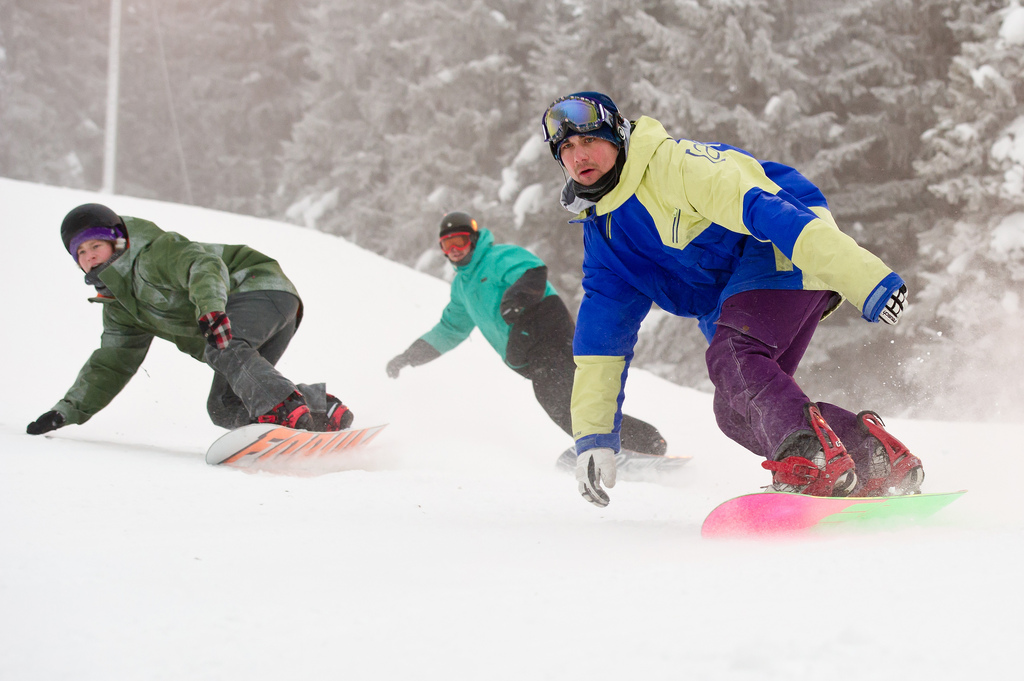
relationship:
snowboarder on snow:
[24, 204, 355, 434] [7, 169, 1021, 671]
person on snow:
[386, 214, 666, 458] [7, 169, 1021, 671]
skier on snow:
[539, 92, 964, 539] [7, 169, 1021, 671]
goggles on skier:
[540, 95, 615, 144] [517, 78, 969, 539]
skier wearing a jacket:
[539, 92, 964, 539] [564, 150, 889, 326]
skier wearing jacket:
[539, 92, 964, 539] [564, 122, 900, 444]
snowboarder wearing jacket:
[24, 204, 355, 434] [45, 242, 294, 402]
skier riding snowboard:
[539, 92, 964, 539] [697, 491, 968, 539]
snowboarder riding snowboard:
[24, 204, 355, 434] [209, 418, 393, 471]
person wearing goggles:
[376, 214, 670, 487] [423, 227, 484, 251]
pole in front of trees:
[99, 0, 123, 198] [17, 9, 964, 398]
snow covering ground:
[0, 188, 1021, 671] [30, 180, 955, 675]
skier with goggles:
[539, 92, 964, 539] [529, 93, 620, 146]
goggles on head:
[529, 93, 620, 146] [546, 85, 627, 178]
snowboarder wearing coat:
[24, 204, 355, 434] [47, 212, 305, 424]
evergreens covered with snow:
[0, 0, 1024, 424] [2, 0, 1011, 418]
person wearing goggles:
[386, 214, 666, 458] [428, 229, 485, 256]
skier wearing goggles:
[539, 92, 964, 539] [533, 89, 633, 139]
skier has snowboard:
[539, 92, 964, 539] [687, 471, 977, 538]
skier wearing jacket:
[539, 92, 964, 539] [538, 83, 910, 457]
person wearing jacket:
[386, 214, 666, 458] [406, 229, 575, 364]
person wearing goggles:
[386, 214, 666, 458] [438, 214, 482, 256]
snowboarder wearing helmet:
[21, 195, 361, 453] [60, 204, 126, 256]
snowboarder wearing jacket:
[21, 195, 361, 453] [48, 212, 303, 420]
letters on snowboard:
[214, 415, 387, 476] [203, 407, 398, 474]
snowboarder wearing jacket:
[24, 204, 355, 434] [48, 212, 303, 420]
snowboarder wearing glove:
[24, 204, 355, 434] [199, 301, 236, 356]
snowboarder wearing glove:
[24, 204, 355, 434] [21, 404, 71, 430]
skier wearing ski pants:
[539, 92, 964, 539] [709, 284, 932, 475]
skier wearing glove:
[539, 92, 964, 539] [572, 441, 622, 513]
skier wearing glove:
[539, 92, 964, 539] [873, 284, 915, 330]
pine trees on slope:
[0, 0, 1024, 428] [0, 175, 1016, 675]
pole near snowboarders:
[91, 0, 126, 204] [19, 80, 938, 524]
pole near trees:
[91, 0, 126, 204] [0, 1, 1024, 431]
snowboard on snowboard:
[761, 404, 926, 497] [695, 476, 985, 546]